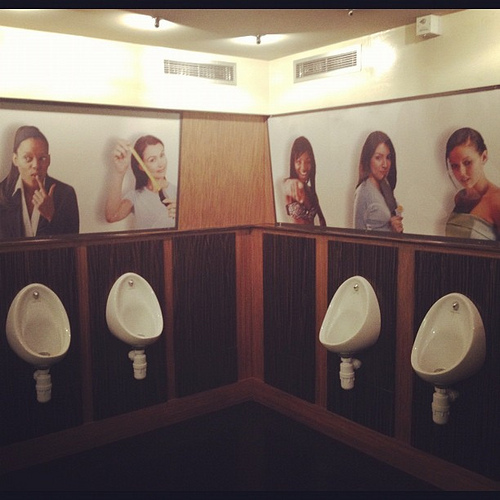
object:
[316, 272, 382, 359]
bowl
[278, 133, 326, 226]
woman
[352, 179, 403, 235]
blue shirt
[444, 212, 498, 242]
gown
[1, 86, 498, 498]
men's restroom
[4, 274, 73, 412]
urinal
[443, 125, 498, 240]
woman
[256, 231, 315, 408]
panel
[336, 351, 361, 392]
pipes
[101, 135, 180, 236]
woman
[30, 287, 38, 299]
button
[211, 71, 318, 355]
corner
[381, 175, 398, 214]
knife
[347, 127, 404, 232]
woman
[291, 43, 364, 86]
plates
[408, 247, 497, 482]
panels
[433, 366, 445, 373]
drain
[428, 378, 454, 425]
pipe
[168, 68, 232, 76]
vent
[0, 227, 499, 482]
wood panels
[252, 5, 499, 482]
wall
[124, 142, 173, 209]
tape measure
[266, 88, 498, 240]
picture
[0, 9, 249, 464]
wall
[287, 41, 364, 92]
vent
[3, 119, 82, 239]
women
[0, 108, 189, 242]
picture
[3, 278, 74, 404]
urinal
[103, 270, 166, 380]
urinal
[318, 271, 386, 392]
urinal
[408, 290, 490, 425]
urinal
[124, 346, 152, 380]
pipe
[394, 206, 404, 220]
object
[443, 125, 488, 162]
hair bun